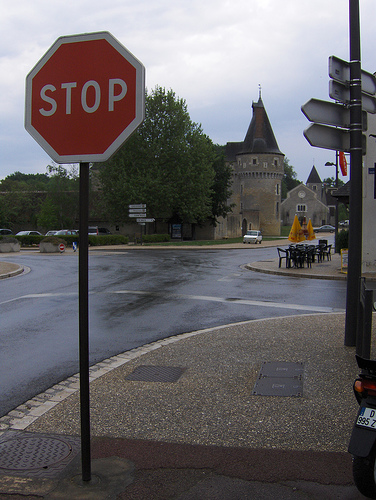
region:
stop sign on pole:
[22, 23, 145, 175]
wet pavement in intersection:
[130, 253, 211, 318]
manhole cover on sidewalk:
[4, 430, 77, 475]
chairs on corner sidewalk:
[275, 236, 337, 270]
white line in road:
[179, 285, 239, 310]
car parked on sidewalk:
[240, 224, 269, 250]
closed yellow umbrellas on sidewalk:
[283, 211, 316, 248]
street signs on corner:
[120, 196, 157, 241]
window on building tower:
[245, 153, 264, 172]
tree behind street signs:
[122, 173, 173, 200]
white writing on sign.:
[43, 68, 123, 114]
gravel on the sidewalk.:
[192, 387, 233, 440]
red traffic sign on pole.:
[44, 45, 126, 139]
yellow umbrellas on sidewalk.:
[289, 214, 319, 237]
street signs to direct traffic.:
[127, 201, 153, 221]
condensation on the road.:
[139, 255, 201, 297]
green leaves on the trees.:
[149, 124, 181, 172]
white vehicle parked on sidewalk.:
[243, 232, 262, 241]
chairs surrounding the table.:
[280, 248, 313, 266]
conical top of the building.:
[248, 106, 274, 147]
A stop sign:
[32, 7, 105, 169]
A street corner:
[46, 330, 146, 474]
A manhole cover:
[17, 406, 51, 478]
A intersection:
[33, 331, 96, 378]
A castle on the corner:
[217, 95, 318, 260]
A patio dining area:
[249, 199, 337, 273]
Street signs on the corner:
[108, 201, 170, 235]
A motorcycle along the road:
[332, 368, 374, 459]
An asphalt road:
[113, 253, 156, 330]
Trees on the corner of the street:
[129, 142, 211, 256]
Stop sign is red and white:
[18, 55, 150, 155]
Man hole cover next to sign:
[8, 415, 62, 484]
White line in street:
[130, 276, 264, 337]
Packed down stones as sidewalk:
[144, 398, 298, 465]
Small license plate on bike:
[346, 395, 363, 440]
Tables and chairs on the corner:
[275, 227, 323, 279]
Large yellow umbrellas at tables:
[281, 211, 326, 257]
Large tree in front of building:
[123, 132, 246, 221]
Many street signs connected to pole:
[309, 22, 374, 177]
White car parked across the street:
[237, 207, 276, 271]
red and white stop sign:
[16, 27, 149, 185]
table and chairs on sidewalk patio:
[273, 207, 339, 278]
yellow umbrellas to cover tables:
[280, 210, 324, 244]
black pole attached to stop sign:
[70, 159, 101, 483]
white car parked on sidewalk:
[241, 227, 266, 246]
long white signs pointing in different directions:
[121, 195, 156, 246]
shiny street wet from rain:
[123, 251, 218, 325]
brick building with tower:
[138, 85, 286, 239]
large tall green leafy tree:
[119, 85, 224, 248]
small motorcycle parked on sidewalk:
[348, 335, 375, 495]